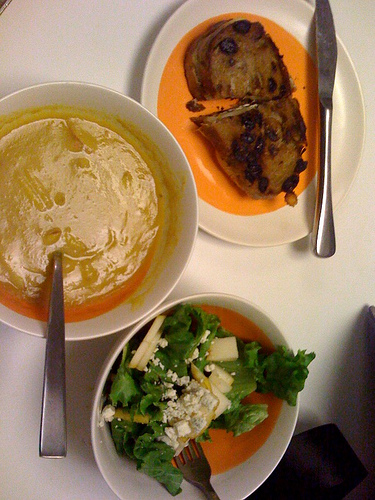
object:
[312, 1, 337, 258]
knife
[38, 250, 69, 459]
spoon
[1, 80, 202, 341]
soup bowl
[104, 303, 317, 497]
lettuce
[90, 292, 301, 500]
bowl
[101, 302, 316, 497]
salad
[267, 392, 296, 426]
bowl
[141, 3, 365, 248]
white edge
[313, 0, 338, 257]
butterknife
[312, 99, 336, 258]
handle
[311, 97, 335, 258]
glare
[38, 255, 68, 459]
silver handle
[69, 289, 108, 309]
orange liquid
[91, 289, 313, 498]
white bowl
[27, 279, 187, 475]
shadow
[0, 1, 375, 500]
table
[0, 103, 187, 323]
soup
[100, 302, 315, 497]
vegetable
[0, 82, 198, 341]
bowl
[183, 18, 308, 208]
bread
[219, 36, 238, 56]
raisin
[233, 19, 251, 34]
raisin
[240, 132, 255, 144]
raisin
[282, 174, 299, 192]
raisin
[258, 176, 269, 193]
raisin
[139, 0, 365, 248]
plate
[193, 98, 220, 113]
wall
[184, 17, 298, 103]
bread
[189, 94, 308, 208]
bread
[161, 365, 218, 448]
cheese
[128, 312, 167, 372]
tofu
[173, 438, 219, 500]
fork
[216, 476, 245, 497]
white bowl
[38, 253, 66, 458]
handle